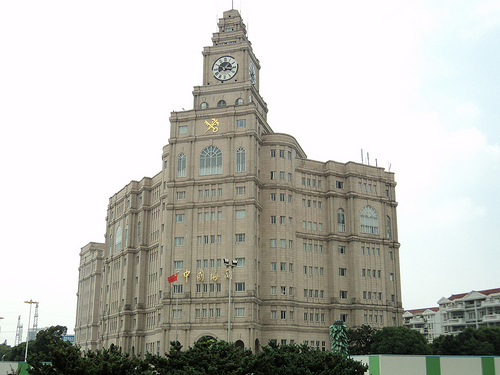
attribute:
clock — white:
[211, 57, 238, 81]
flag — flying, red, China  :
[168, 272, 180, 284]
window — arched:
[198, 147, 226, 179]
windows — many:
[174, 145, 246, 177]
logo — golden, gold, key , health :
[202, 118, 221, 134]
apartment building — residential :
[401, 287, 499, 345]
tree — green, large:
[330, 322, 354, 357]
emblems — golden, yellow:
[182, 269, 230, 283]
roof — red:
[404, 288, 499, 314]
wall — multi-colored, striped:
[2, 356, 499, 375]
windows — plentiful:
[197, 209, 222, 222]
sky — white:
[4, 4, 458, 331]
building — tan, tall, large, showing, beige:
[60, 3, 406, 363]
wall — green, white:
[348, 353, 498, 373]